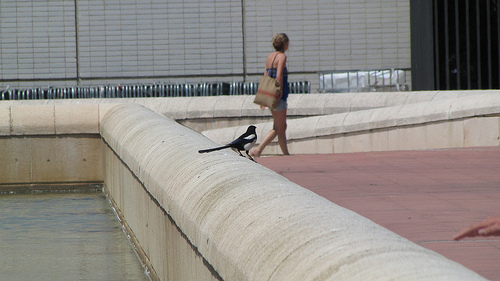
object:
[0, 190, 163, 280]
water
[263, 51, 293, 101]
skirt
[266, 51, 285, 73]
back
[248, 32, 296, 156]
person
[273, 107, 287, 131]
thigh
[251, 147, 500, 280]
ground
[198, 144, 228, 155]
tail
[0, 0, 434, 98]
building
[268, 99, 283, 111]
shorts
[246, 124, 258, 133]
head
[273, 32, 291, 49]
head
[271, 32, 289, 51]
hair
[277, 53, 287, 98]
arm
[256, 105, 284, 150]
legs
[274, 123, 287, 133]
knees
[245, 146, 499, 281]
sidewalk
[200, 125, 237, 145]
brick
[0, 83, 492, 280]
building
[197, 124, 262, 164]
bird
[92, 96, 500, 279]
ledge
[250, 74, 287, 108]
bag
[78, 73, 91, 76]
brick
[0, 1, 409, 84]
wall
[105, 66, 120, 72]
brick